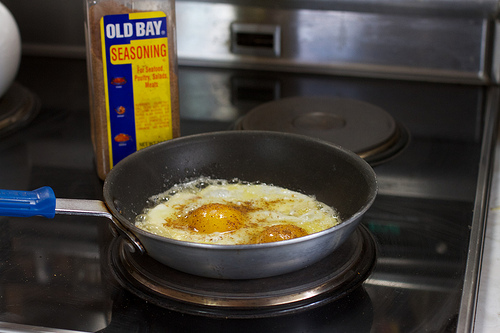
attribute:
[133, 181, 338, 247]
eggs — cooking, fried, frying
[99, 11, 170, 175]
label — traditional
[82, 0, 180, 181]
seasoning — old bay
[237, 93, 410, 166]
burner — black, empty, unused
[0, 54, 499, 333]
stove — electric, black, shiny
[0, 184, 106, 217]
handle — blue, plastic, silver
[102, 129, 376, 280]
pan — high quality, teflon, filled, black, frying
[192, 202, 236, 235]
yolk — yellow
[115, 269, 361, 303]
plate — metal, smalll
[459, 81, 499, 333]
border — gray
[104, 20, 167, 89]
words — old bay, white